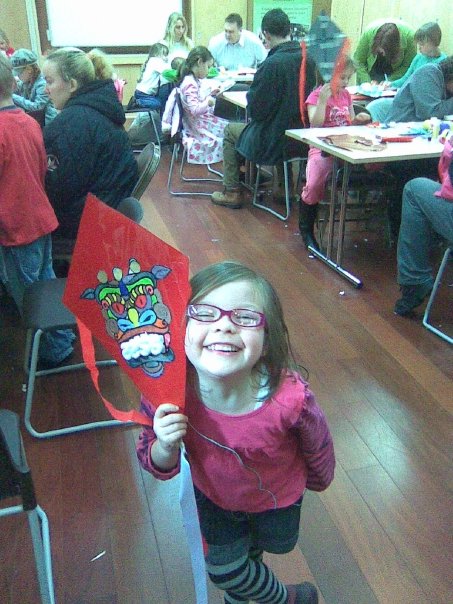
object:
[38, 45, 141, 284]
person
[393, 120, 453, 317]
person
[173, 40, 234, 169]
girl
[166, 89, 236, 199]
chair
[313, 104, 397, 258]
chair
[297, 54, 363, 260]
girl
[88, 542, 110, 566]
trash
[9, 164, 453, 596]
floor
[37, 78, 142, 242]
hoodie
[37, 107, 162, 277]
chair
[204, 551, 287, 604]
leggings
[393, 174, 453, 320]
legs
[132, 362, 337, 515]
shirt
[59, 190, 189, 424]
kite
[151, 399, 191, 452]
hand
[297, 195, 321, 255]
boots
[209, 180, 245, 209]
boot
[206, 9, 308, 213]
person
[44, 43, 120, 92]
hair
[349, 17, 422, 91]
person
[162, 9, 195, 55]
hair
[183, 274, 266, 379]
face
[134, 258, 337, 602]
child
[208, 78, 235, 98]
book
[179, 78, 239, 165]
dress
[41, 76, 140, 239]
coat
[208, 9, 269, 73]
man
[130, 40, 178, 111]
girl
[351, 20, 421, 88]
jacket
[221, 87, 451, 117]
table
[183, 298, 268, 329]
glasses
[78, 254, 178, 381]
design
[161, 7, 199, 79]
people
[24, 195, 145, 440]
chair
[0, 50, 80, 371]
person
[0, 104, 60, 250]
shirt